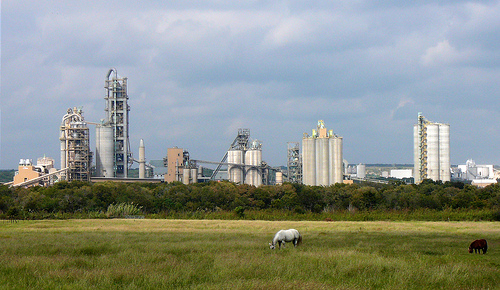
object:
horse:
[267, 227, 304, 249]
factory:
[0, 66, 500, 208]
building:
[405, 110, 451, 180]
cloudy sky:
[1, 2, 498, 178]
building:
[94, 66, 137, 183]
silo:
[243, 138, 263, 189]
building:
[222, 129, 267, 188]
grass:
[1, 210, 500, 288]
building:
[452, 157, 498, 185]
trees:
[0, 178, 499, 221]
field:
[0, 210, 500, 290]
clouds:
[148, 11, 291, 68]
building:
[165, 145, 202, 186]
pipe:
[106, 68, 117, 119]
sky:
[0, 0, 497, 171]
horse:
[324, 218, 334, 221]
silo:
[226, 148, 244, 188]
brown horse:
[463, 238, 487, 255]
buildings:
[158, 145, 202, 184]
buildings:
[297, 119, 344, 189]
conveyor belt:
[190, 155, 263, 171]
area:
[0, 176, 499, 223]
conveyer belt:
[210, 133, 237, 174]